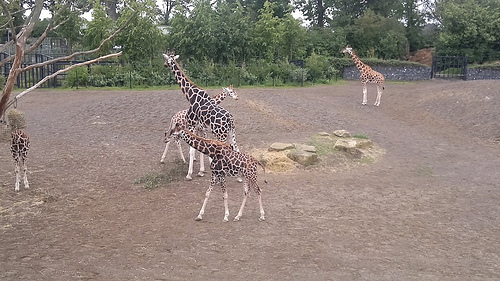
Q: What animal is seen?
A: Giraffes.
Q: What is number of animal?
A: Three.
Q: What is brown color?
A: Ground.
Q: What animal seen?
A: Giraffe.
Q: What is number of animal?
A: Five.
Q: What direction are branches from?
A: Left.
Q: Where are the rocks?
A: In middle.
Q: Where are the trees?
A: Around giraffes.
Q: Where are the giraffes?
A: In pen.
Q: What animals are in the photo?
A: Giraffes.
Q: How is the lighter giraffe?
A: It is tall.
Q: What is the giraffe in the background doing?
A: It is standing up.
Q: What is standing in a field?
A: Giraffes.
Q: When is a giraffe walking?
A: During day time.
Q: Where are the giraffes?
A: Walking in a field.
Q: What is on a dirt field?
A: Giraffes.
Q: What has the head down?
A: A giraffe.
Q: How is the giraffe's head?
A: It is up.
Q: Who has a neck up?
A: Giraffe.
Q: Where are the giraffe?
A: In the fence.